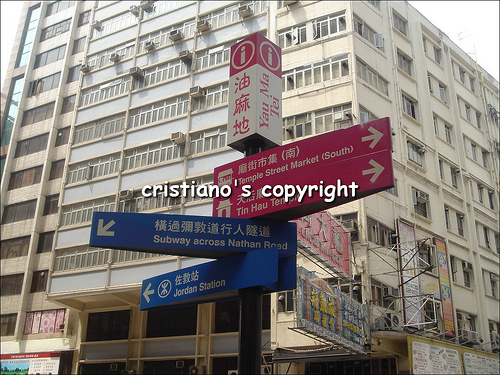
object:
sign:
[225, 32, 282, 152]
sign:
[208, 115, 394, 217]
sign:
[291, 211, 353, 279]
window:
[441, 123, 452, 147]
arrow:
[361, 126, 384, 148]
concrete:
[3, 185, 36, 206]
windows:
[460, 258, 473, 290]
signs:
[87, 206, 302, 313]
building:
[0, 1, 498, 374]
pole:
[239, 287, 265, 373]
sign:
[230, 33, 285, 145]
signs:
[207, 117, 401, 220]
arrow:
[360, 157, 384, 185]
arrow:
[97, 216, 117, 238]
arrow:
[138, 280, 154, 304]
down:
[91, 213, 119, 238]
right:
[126, 290, 175, 353]